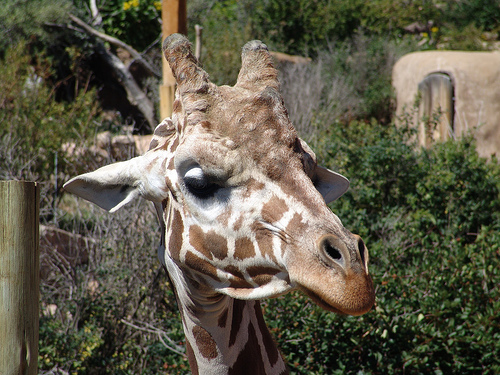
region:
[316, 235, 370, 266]
The nose of the giraffe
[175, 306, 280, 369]
The neck of the giraffe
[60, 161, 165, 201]
The right ear of the giraffe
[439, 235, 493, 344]
Green leaves behind the giraffe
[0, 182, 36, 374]
A brown pole near the giraffe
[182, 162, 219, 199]
The eye of the giraffe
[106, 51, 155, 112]
Tree branches behind the giraffe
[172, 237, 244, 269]
The fur on the giraffe is brown and white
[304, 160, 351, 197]
The left ear of the giraffe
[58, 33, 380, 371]
A giraffe near some trees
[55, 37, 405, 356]
Brown and white giraffe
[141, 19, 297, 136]
The giraffe has horns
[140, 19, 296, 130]
Two brown horns with black tips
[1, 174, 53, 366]
Tall wooden post next to the giraffe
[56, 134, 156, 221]
Giraffe has white ears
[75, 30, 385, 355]
The giraffe has spots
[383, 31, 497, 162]
Large tan rock behind bushes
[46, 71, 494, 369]
Green and brown bushes behind giraffe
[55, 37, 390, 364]
The spots are different sizes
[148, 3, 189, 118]
The post is brown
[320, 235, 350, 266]
Right nostril of an adult giraffe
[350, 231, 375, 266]
Left nostril of an adult giraffe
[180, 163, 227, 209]
Right eye of an adult giraffe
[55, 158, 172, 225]
Right ear of an adult giraffe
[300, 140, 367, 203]
Left ear of an adult giraffe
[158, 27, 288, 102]
Horns of an adult giraffe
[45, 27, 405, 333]
Healthy adult giraffe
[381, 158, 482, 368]
Green and red shrubs in the background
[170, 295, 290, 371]
Top portion of the giraffe neck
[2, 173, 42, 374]
Wooden post in the background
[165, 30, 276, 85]
the horns on the giraffe's head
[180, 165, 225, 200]
the right eye on the giraffe's head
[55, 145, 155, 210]
the right ear on the giraffe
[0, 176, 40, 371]
the wooden post next to the giraffe's head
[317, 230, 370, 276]
the giraffe's nostrils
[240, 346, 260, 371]
the brown area on the giraffe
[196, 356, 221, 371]
the white area on the giraffe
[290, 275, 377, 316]
the giraffe's mouth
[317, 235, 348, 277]
the giraffe's right nostril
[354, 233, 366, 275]
the giraffe's left nostril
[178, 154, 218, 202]
the right eye of the giraffe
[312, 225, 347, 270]
the right nostril of the giraffe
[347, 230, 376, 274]
the left nostril of the giraffe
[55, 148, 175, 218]
the right ear of the giraffe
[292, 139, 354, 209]
the left ear of the giraffe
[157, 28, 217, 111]
the right horn of the giraffe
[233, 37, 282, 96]
the left horn of the giraffe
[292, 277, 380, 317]
the mouth of the giraffe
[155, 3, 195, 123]
the wooden pole behind the giraffe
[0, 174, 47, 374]
the wooden pole beside the giraffe